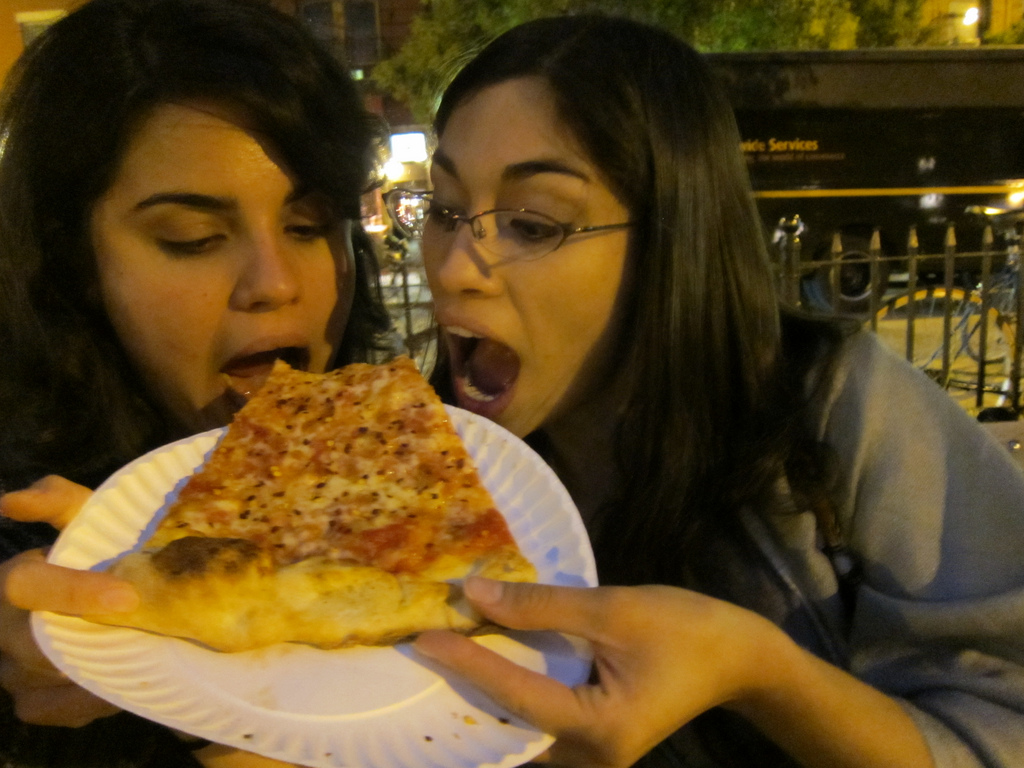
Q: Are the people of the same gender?
A: Yes, all the people are female.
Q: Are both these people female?
A: Yes, all the people are female.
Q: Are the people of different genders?
A: No, all the people are female.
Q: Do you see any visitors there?
A: No, there are no visitors.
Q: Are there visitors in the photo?
A: No, there are no visitors.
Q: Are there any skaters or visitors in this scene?
A: No, there are no visitors or skaters.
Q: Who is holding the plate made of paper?
A: The girl is holding the plate.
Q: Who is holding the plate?
A: The girl is holding the plate.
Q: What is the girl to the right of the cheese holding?
A: The girl is holding the plate.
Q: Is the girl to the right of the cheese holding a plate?
A: Yes, the girl is holding a plate.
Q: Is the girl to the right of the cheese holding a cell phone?
A: No, the girl is holding a plate.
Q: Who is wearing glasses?
A: The girl is wearing glasses.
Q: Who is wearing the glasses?
A: The girl is wearing glasses.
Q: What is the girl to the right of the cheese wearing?
A: The girl is wearing glasses.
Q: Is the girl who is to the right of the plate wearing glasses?
A: Yes, the girl is wearing glasses.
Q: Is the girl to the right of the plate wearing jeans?
A: No, the girl is wearing glasses.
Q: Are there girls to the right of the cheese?
A: Yes, there is a girl to the right of the cheese.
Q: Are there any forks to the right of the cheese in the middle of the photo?
A: No, there is a girl to the right of the cheese.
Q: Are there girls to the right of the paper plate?
A: Yes, there is a girl to the right of the plate.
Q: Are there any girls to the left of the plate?
A: No, the girl is to the right of the plate.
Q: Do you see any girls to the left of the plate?
A: No, the girl is to the right of the plate.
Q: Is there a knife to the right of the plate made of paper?
A: No, there is a girl to the right of the plate.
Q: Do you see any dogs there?
A: No, there are no dogs.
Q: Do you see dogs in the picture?
A: No, there are no dogs.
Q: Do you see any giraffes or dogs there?
A: No, there are no dogs or giraffes.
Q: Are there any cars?
A: No, there are no cars.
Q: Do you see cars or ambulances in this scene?
A: No, there are no cars or ambulances.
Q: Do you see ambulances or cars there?
A: No, there are no cars or ambulances.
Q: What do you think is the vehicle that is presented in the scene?
A: The vehicle is a van.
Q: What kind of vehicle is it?
A: The vehicle is a van.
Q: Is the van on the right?
A: Yes, the van is on the right of the image.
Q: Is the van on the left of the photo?
A: No, the van is on the right of the image.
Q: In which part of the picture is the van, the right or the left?
A: The van is on the right of the image.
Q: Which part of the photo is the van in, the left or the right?
A: The van is on the right of the image.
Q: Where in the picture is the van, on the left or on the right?
A: The van is on the right of the image.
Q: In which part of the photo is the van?
A: The van is on the right of the image.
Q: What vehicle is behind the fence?
A: The vehicle is a van.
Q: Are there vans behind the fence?
A: Yes, there is a van behind the fence.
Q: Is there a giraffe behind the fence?
A: No, there is a van behind the fence.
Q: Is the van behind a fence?
A: Yes, the van is behind a fence.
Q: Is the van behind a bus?
A: No, the van is behind a fence.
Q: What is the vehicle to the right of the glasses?
A: The vehicle is a van.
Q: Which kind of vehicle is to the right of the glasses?
A: The vehicle is a van.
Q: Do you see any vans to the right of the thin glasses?
A: Yes, there is a van to the right of the glasses.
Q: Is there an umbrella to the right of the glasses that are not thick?
A: No, there is a van to the right of the glasses.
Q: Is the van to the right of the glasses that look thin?
A: Yes, the van is to the right of the glasses.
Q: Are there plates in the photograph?
A: Yes, there is a plate.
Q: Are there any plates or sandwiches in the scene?
A: Yes, there is a plate.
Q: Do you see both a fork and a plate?
A: No, there is a plate but no forks.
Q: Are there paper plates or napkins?
A: Yes, there is a paper plate.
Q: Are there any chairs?
A: No, there are no chairs.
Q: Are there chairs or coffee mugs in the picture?
A: No, there are no chairs or coffee mugs.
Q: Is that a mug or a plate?
A: That is a plate.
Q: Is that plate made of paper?
A: Yes, the plate is made of paper.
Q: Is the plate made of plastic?
A: No, the plate is made of paper.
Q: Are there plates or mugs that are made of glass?
A: No, there is a plate but it is made of paper.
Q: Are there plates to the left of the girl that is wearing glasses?
A: Yes, there is a plate to the left of the girl.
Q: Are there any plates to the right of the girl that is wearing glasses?
A: No, the plate is to the left of the girl.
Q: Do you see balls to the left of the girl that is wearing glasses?
A: No, there is a plate to the left of the girl.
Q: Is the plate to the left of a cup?
A: No, the plate is to the left of the girl.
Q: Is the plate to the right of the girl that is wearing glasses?
A: No, the plate is to the left of the girl.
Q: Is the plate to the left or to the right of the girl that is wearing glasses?
A: The plate is to the left of the girl.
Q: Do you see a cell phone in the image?
A: No, there are no cell phones.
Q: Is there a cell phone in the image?
A: No, there are no cell phones.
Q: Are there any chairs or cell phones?
A: No, there are no cell phones or chairs.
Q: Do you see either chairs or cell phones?
A: No, there are no cell phones or chairs.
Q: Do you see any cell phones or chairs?
A: No, there are no cell phones or chairs.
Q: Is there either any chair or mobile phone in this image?
A: No, there are no cell phones or chairs.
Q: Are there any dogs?
A: No, there are no dogs.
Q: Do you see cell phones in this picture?
A: No, there are no cell phones.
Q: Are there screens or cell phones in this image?
A: No, there are no cell phones or screens.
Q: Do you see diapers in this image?
A: No, there are no diapers.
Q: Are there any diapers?
A: No, there are no diapers.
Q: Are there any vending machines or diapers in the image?
A: No, there are no diapers or vending machines.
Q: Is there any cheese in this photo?
A: Yes, there is cheese.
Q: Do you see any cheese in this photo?
A: Yes, there is cheese.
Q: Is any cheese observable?
A: Yes, there is cheese.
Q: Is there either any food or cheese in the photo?
A: Yes, there is cheese.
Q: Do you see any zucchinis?
A: No, there are no zucchinis.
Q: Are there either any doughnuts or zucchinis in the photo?
A: No, there are no zucchinis or doughnuts.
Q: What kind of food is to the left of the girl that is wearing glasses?
A: The food is cheese.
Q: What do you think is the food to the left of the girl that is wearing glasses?
A: The food is cheese.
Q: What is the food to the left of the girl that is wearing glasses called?
A: The food is cheese.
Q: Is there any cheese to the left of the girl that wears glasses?
A: Yes, there is cheese to the left of the girl.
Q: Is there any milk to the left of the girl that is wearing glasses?
A: No, there is cheese to the left of the girl.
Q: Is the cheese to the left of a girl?
A: Yes, the cheese is to the left of a girl.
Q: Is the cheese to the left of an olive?
A: No, the cheese is to the left of a girl.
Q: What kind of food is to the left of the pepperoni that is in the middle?
A: The food is cheese.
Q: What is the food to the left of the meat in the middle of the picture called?
A: The food is cheese.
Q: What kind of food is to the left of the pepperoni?
A: The food is cheese.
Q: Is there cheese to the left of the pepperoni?
A: Yes, there is cheese to the left of the pepperoni.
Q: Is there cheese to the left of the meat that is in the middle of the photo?
A: Yes, there is cheese to the left of the pepperoni.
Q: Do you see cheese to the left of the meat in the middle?
A: Yes, there is cheese to the left of the pepperoni.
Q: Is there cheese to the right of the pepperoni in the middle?
A: No, the cheese is to the left of the pepperoni.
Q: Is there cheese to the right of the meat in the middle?
A: No, the cheese is to the left of the pepperoni.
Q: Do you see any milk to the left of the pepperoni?
A: No, there is cheese to the left of the pepperoni.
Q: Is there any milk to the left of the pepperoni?
A: No, there is cheese to the left of the pepperoni.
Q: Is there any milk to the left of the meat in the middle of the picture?
A: No, there is cheese to the left of the pepperoni.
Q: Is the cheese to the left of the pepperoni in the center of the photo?
A: Yes, the cheese is to the left of the pepperoni.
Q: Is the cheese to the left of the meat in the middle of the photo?
A: Yes, the cheese is to the left of the pepperoni.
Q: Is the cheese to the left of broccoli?
A: No, the cheese is to the left of the pepperoni.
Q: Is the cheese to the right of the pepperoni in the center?
A: No, the cheese is to the left of the pepperoni.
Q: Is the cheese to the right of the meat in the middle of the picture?
A: No, the cheese is to the left of the pepperoni.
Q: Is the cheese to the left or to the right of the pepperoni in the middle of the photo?
A: The cheese is to the left of the pepperoni.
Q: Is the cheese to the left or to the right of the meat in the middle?
A: The cheese is to the left of the pepperoni.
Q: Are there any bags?
A: No, there are no bags.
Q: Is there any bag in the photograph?
A: No, there are no bags.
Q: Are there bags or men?
A: No, there are no bags or men.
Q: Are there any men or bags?
A: No, there are no bags or men.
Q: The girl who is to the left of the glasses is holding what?
A: The girl is holding the plate.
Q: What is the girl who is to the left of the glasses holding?
A: The girl is holding the plate.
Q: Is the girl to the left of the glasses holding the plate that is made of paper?
A: Yes, the girl is holding the plate.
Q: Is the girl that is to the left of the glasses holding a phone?
A: No, the girl is holding the plate.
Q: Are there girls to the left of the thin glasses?
A: Yes, there is a girl to the left of the glasses.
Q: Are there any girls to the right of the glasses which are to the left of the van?
A: No, the girl is to the left of the glasses.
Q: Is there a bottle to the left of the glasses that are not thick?
A: No, there is a girl to the left of the glasses.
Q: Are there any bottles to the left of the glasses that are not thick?
A: No, there is a girl to the left of the glasses.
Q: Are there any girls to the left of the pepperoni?
A: Yes, there is a girl to the left of the pepperoni.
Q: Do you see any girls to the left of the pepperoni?
A: Yes, there is a girl to the left of the pepperoni.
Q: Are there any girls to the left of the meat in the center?
A: Yes, there is a girl to the left of the pepperoni.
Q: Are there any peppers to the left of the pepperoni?
A: No, there is a girl to the left of the pepperoni.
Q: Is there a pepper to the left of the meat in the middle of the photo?
A: No, there is a girl to the left of the pepperoni.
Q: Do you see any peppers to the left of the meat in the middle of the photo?
A: No, there is a girl to the left of the pepperoni.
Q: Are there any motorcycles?
A: No, there are no motorcycles.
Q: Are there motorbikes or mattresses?
A: No, there are no motorbikes or mattresses.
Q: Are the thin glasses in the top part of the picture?
A: Yes, the glasses are in the top of the image.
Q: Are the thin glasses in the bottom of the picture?
A: No, the glasses are in the top of the image.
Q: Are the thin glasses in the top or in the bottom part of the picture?
A: The glasses are in the top of the image.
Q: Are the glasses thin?
A: Yes, the glasses are thin.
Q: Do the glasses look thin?
A: Yes, the glasses are thin.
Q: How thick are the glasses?
A: The glasses are thin.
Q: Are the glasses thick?
A: No, the glasses are thin.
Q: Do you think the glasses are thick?
A: No, the glasses are thin.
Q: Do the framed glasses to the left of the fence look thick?
A: No, the glasses are thin.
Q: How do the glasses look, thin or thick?
A: The glasses are thin.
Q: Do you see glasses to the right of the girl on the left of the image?
A: Yes, there are glasses to the right of the girl.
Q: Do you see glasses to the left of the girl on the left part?
A: No, the glasses are to the right of the girl.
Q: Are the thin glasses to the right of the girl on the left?
A: Yes, the glasses are to the right of the girl.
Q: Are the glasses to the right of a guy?
A: No, the glasses are to the right of the girl.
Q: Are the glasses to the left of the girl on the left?
A: No, the glasses are to the right of the girl.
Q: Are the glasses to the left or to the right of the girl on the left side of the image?
A: The glasses are to the right of the girl.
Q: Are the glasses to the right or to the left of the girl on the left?
A: The glasses are to the right of the girl.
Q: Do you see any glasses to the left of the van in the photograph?
A: Yes, there are glasses to the left of the van.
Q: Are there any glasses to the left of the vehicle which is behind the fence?
A: Yes, there are glasses to the left of the van.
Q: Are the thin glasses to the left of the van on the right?
A: Yes, the glasses are to the left of the van.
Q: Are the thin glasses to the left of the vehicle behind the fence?
A: Yes, the glasses are to the left of the van.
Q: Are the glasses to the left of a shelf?
A: No, the glasses are to the left of the van.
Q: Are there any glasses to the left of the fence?
A: Yes, there are glasses to the left of the fence.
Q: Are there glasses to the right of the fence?
A: No, the glasses are to the left of the fence.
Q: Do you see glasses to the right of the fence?
A: No, the glasses are to the left of the fence.